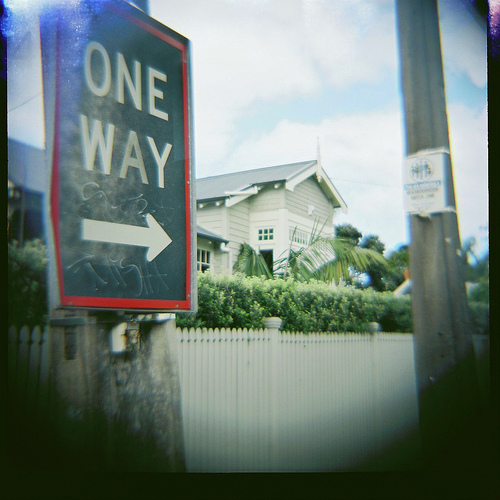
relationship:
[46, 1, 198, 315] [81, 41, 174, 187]
sign with words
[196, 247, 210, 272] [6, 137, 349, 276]
window on house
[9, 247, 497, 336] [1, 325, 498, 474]
bushes behind fence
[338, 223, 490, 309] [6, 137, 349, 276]
trees near house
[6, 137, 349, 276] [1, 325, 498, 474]
house in front of fence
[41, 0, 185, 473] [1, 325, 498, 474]
post near fence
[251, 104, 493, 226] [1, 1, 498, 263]
clouds in sky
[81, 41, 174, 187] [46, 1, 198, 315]
words on sign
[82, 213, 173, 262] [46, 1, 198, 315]
arrow on sign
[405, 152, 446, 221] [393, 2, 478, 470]
poster on pole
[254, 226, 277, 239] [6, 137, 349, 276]
window on house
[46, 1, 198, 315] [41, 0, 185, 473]
sign on pole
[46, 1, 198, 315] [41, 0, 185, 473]
sign on post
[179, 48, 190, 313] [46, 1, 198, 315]
red line on sign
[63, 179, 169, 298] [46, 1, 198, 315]
graffitti on sign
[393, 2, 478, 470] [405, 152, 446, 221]
pole with poster